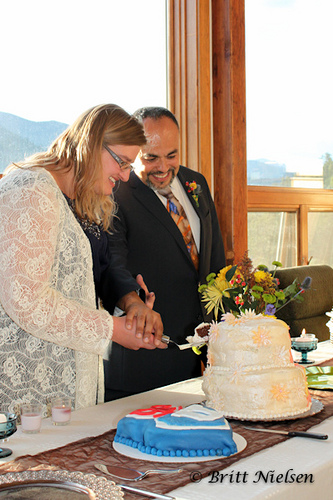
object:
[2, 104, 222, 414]
couple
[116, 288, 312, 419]
cutting the cake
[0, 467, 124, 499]
stainless steel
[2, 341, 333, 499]
on the table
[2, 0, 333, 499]
photo is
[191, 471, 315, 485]
by britt nielsen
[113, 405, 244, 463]
blue cake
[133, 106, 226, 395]
groom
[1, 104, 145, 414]
with the bride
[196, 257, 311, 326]
bouquet of flowers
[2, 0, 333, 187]
large windows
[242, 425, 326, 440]
sharp steak knife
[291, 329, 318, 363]
green candle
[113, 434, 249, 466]
white plate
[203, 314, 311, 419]
wedding cake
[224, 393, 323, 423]
silver platter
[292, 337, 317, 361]
candle holder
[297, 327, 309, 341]
lit candle in it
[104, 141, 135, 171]
reading glasses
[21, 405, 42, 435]
two candle holders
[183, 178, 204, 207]
lapel of his jacket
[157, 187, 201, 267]
and necktie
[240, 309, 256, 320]
flowers on it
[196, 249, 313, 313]
colorful arrangement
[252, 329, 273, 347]
orange flowers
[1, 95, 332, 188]
mountains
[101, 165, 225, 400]
suit and tie